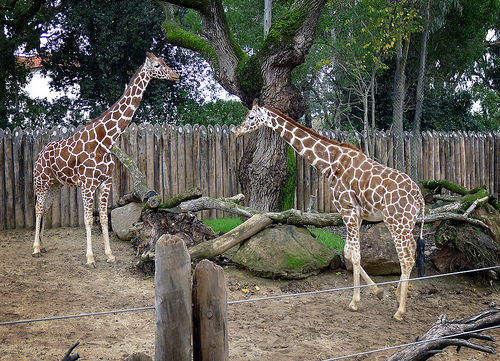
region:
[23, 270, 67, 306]
this is the ground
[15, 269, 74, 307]
the ground is sandy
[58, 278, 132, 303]
the sand is brown in color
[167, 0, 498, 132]
these are some trees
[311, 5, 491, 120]
the trees are tall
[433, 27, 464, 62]
the leaves are green in color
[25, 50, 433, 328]
these are two giraffes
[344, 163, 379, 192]
the fur is brown in color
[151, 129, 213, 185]
this is a fence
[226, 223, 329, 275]
this is a rock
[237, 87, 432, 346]
the giraffe is brown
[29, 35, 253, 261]
the giraffe is brown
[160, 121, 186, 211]
the brown wooden fence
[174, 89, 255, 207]
the brown wooden fence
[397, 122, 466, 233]
the brown wooden fence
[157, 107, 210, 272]
the brown wooden fence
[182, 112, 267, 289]
the brown wooden fence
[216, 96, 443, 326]
This is a giraffe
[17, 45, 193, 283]
This is a giraffe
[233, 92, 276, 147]
Head of a giraffe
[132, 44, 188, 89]
Head of a giraffe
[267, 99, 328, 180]
Neck of a giraffe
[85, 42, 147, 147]
Neck of a giraffe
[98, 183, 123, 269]
Leg of a giraffe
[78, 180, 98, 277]
Leg of a giraffe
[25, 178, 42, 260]
Leg of a giraffe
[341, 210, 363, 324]
Leg of a giraffe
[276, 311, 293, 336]
part of a ground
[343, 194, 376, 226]
part of a giraffe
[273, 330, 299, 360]
part of a ground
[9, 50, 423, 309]
two giraffes standing together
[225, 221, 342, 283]
moss covered rocks between giraffes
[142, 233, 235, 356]
wood posts of wire fence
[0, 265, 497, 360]
two lines of wire of fence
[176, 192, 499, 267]
log laying on rocks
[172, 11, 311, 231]
moss covered tree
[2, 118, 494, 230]
wood fence behind giraffes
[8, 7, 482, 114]
trees behind fence line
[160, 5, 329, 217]
tree inside giraffe enclosure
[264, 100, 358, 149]
brown mane of giraffe standing in front of rocks